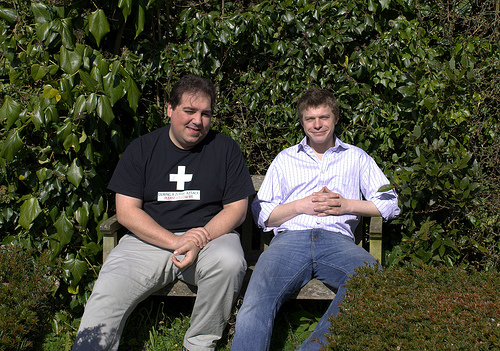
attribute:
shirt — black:
[133, 138, 232, 206]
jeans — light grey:
[104, 262, 140, 310]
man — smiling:
[108, 74, 252, 304]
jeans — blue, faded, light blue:
[273, 245, 354, 314]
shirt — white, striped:
[272, 156, 382, 190]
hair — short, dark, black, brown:
[175, 75, 216, 97]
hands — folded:
[169, 227, 202, 272]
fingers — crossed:
[308, 188, 347, 219]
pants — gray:
[204, 256, 233, 329]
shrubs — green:
[425, 147, 488, 267]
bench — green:
[251, 176, 260, 249]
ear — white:
[165, 101, 173, 117]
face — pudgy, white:
[171, 99, 211, 141]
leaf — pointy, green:
[88, 10, 109, 49]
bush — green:
[247, 19, 338, 66]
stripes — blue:
[325, 170, 365, 190]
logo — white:
[156, 163, 207, 206]